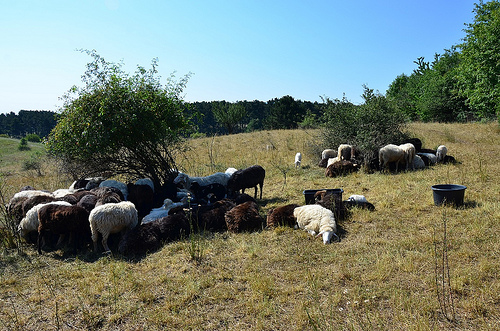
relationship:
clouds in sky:
[1, 0, 499, 115] [2, 0, 482, 101]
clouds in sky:
[1, 0, 499, 115] [0, 0, 498, 116]